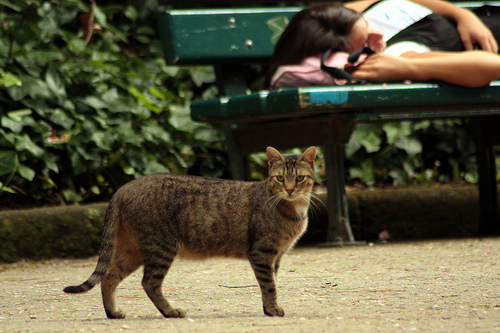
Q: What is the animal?
A: A cat.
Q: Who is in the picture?
A: A woman and a cat.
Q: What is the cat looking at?
A: The camera.